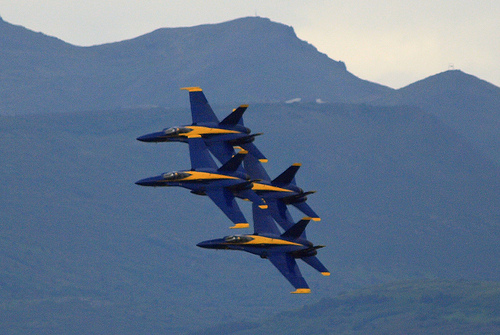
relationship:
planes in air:
[145, 103, 332, 313] [345, 152, 450, 267]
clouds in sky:
[89, 13, 120, 23] [0, 0, 497, 334]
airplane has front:
[194, 202, 331, 295] [193, 225, 238, 259]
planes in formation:
[119, 69, 337, 307] [124, 74, 345, 306]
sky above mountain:
[296, 8, 498, 85] [384, 71, 498, 132]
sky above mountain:
[296, 8, 498, 85] [3, 15, 382, 109]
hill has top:
[7, 19, 450, 115] [210, 6, 303, 57]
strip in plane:
[244, 232, 294, 249] [200, 207, 330, 292]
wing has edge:
[183, 83, 222, 126] [182, 81, 199, 118]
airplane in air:
[200, 206, 331, 299] [12, 49, 491, 318]